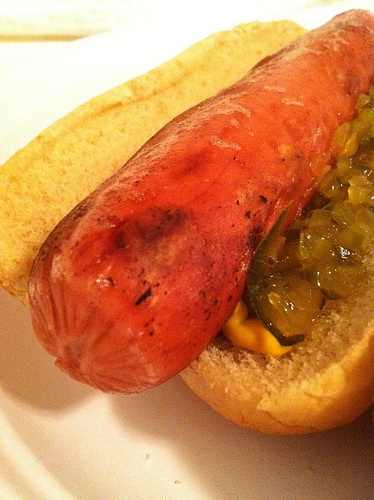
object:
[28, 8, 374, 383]
cooked hotdog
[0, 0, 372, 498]
table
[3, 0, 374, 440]
bun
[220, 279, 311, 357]
mustard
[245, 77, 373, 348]
relish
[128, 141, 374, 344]
spot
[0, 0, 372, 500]
plate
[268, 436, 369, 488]
crumb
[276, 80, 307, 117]
bubble